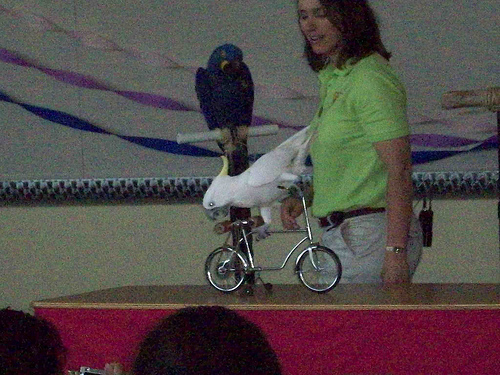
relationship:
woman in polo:
[288, 6, 437, 291] [306, 48, 420, 217]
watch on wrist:
[386, 244, 410, 258] [371, 232, 425, 274]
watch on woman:
[386, 244, 410, 258] [271, 0, 436, 291]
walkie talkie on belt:
[417, 187, 433, 250] [314, 200, 391, 231]